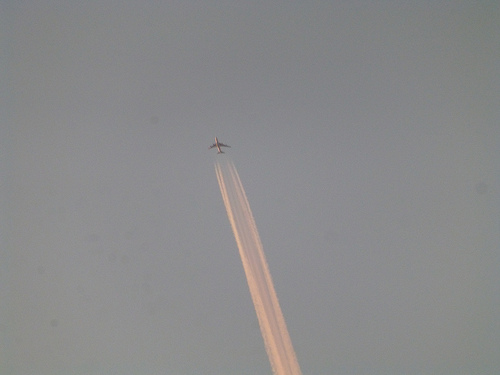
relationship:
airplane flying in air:
[208, 136, 231, 154] [26, 16, 465, 291]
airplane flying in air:
[208, 136, 231, 154] [76, 76, 402, 134]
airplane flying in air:
[208, 136, 231, 154] [2, 2, 497, 374]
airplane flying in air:
[208, 136, 231, 154] [28, 63, 477, 310]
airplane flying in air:
[208, 136, 231, 154] [35, 50, 393, 197]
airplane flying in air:
[208, 135, 231, 155] [54, 42, 479, 171]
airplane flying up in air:
[208, 136, 231, 154] [31, 45, 483, 134]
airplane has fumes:
[208, 136, 231, 154] [210, 162, 310, 373]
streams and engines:
[214, 161, 303, 373] [211, 144, 229, 150]